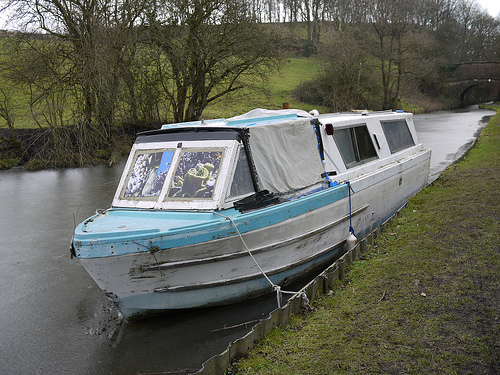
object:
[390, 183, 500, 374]
ground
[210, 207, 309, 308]
rope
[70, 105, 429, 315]
boat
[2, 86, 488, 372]
water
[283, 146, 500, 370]
shore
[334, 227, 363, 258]
bumper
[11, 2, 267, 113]
trees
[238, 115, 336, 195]
canvas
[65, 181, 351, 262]
blue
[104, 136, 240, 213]
window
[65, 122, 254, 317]
front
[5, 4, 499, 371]
light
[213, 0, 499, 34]
trees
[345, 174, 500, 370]
grass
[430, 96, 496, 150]
body of water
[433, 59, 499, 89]
bridge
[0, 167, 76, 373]
river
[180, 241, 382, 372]
fence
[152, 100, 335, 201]
fabric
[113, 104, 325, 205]
cabin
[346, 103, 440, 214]
white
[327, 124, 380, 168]
window